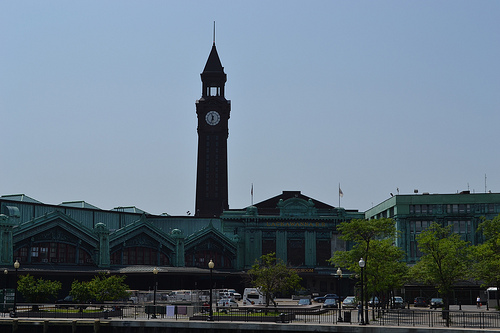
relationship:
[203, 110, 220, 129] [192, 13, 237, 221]
clock on tower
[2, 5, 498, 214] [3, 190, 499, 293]
sky above buildings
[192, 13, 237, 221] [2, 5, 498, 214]
tower under sky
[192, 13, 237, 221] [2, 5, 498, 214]
tower below sky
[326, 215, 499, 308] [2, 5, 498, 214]
trees under sky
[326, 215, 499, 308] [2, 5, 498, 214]
trees below sky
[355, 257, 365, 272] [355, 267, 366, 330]
lamp on post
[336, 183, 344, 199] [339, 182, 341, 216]
flag on flag pole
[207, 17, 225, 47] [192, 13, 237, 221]
lightning rod on top of tower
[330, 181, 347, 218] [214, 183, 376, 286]
pole on building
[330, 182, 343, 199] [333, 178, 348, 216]
flag on flag pole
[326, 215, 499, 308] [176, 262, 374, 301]
trees in front of buiding